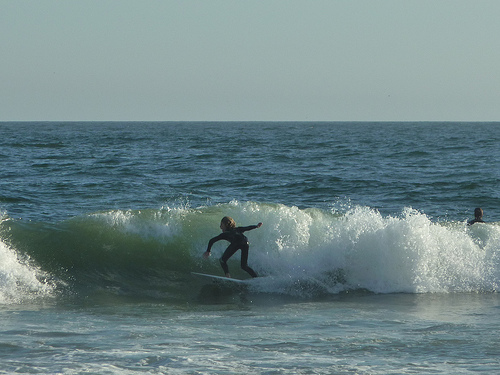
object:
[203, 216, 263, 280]
sufer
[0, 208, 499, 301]
wave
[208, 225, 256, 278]
wetsuit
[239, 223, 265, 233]
arm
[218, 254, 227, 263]
knees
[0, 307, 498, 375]
water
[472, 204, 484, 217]
head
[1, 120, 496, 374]
water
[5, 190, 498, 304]
high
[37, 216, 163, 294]
break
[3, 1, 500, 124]
sky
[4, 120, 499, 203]
water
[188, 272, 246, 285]
surfboard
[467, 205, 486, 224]
person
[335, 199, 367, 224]
foam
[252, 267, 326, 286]
trail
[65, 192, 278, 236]
swell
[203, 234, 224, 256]
arm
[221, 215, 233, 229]
hair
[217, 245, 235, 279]
leg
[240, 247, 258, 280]
leg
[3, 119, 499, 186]
distance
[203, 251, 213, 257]
hand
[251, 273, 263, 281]
foot